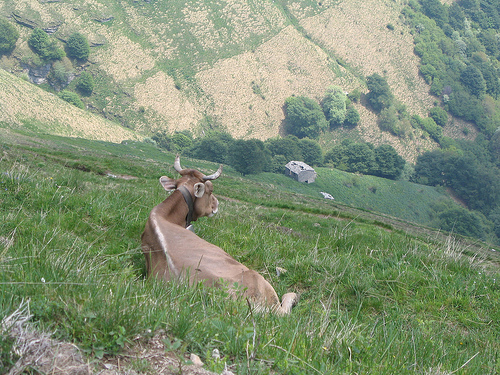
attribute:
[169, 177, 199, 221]
collar — black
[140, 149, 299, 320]
cow — white, brown